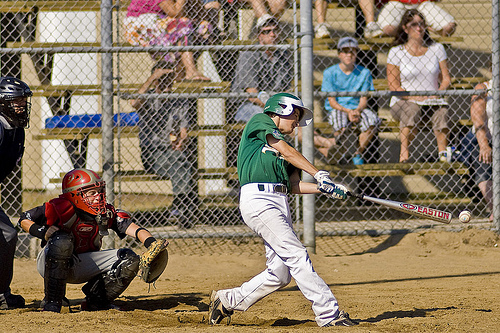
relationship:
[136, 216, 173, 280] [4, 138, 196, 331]
mitt of catcher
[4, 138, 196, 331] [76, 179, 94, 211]
catcher has mask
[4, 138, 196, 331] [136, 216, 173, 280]
catcher has mitt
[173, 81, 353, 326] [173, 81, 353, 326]
men playing boy